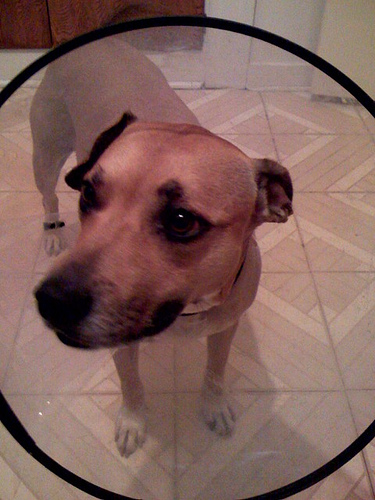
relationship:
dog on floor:
[30, 34, 293, 460] [2, 82, 375, 498]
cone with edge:
[2, 17, 373, 499] [0, 10, 373, 496]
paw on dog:
[111, 401, 152, 458] [30, 34, 293, 460]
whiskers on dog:
[93, 306, 168, 355] [30, 34, 293, 460]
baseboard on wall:
[250, 58, 314, 93] [0, 2, 311, 86]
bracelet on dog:
[41, 218, 70, 232] [30, 34, 293, 460]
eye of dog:
[158, 205, 212, 246] [30, 34, 293, 460]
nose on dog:
[32, 282, 87, 324] [30, 34, 293, 460]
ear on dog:
[251, 155, 294, 225] [30, 34, 293, 460]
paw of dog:
[111, 401, 152, 458] [30, 34, 293, 460]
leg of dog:
[203, 330, 241, 404] [30, 34, 293, 460]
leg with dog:
[203, 330, 241, 404] [30, 34, 293, 460]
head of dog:
[34, 114, 295, 352] [30, 34, 293, 460]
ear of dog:
[251, 155, 294, 225] [30, 34, 293, 460]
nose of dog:
[32, 282, 87, 324] [30, 34, 293, 460]